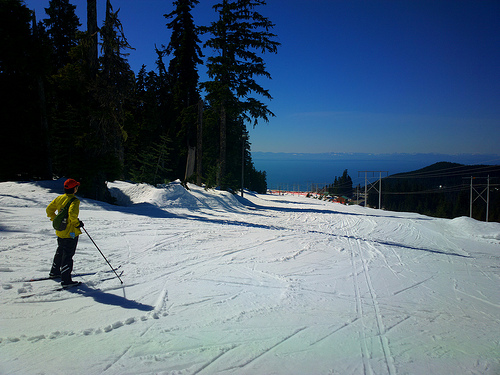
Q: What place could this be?
A: It is a field.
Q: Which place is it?
A: It is a field.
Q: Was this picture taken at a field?
A: Yes, it was taken in a field.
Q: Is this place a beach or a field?
A: It is a field.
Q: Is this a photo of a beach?
A: No, the picture is showing a field.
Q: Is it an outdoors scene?
A: Yes, it is outdoors.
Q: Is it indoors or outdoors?
A: It is outdoors.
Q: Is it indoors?
A: No, it is outdoors.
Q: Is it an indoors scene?
A: No, it is outdoors.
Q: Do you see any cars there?
A: No, there are no cars.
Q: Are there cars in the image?
A: No, there are no cars.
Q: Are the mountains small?
A: Yes, the mountains are small.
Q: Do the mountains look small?
A: Yes, the mountains are small.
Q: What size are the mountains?
A: The mountains are small.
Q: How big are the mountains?
A: The mountains are small.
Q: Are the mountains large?
A: No, the mountains are small.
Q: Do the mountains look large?
A: No, the mountains are small.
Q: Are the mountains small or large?
A: The mountains are small.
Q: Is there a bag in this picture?
A: Yes, there is a bag.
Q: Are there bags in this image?
A: Yes, there is a bag.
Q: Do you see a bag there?
A: Yes, there is a bag.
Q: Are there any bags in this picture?
A: Yes, there is a bag.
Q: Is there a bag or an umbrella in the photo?
A: Yes, there is a bag.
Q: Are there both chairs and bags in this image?
A: No, there is a bag but no chairs.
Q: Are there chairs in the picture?
A: No, there are no chairs.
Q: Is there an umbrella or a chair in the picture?
A: No, there are no chairs or umbrellas.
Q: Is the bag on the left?
A: Yes, the bag is on the left of the image.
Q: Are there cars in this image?
A: No, there are no cars.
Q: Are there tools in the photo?
A: No, there are no tools.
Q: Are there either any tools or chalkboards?
A: No, there are no tools or chalkboards.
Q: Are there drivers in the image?
A: No, there are no drivers.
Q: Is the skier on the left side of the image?
A: Yes, the skier is on the left of the image.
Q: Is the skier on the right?
A: No, the skier is on the left of the image.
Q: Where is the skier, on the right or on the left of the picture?
A: The skier is on the left of the image.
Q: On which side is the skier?
A: The skier is on the left of the image.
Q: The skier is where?
A: The skier is in the field.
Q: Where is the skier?
A: The skier is in the field.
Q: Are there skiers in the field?
A: Yes, there is a skier in the field.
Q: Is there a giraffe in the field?
A: No, there is a skier in the field.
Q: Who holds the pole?
A: The skier holds the pole.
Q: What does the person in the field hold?
A: The skier holds the pole.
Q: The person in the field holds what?
A: The skier holds the pole.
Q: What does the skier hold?
A: The skier holds the pole.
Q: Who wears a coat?
A: The skier wears a coat.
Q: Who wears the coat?
A: The skier wears a coat.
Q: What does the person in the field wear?
A: The skier wears a coat.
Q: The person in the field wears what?
A: The skier wears a coat.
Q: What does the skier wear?
A: The skier wears a coat.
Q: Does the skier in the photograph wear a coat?
A: Yes, the skier wears a coat.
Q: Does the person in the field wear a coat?
A: Yes, the skier wears a coat.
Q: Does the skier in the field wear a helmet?
A: No, the skier wears a coat.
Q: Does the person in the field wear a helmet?
A: No, the skier wears a coat.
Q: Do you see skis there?
A: Yes, there are skis.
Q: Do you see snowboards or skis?
A: Yes, there are skis.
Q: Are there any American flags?
A: No, there are no American flags.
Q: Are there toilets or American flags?
A: No, there are no American flags or toilets.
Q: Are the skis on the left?
A: Yes, the skis are on the left of the image.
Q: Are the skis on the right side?
A: No, the skis are on the left of the image.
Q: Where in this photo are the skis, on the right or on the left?
A: The skis are on the left of the image.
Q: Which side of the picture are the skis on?
A: The skis are on the left of the image.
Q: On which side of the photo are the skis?
A: The skis are on the left of the image.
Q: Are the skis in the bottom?
A: Yes, the skis are in the bottom of the image.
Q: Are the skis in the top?
A: No, the skis are in the bottom of the image.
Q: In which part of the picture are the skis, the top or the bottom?
A: The skis are in the bottom of the image.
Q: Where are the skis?
A: The skis are in the field.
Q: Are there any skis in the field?
A: Yes, there are skis in the field.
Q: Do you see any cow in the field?
A: No, there are skis in the field.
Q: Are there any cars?
A: No, there are no cars.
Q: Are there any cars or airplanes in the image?
A: No, there are no cars or airplanes.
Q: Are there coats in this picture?
A: Yes, there is a coat.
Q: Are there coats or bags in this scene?
A: Yes, there is a coat.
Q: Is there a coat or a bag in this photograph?
A: Yes, there is a coat.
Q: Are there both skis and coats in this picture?
A: Yes, there are both a coat and skis.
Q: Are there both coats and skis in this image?
A: Yes, there are both a coat and skis.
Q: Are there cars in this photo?
A: No, there are no cars.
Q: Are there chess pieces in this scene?
A: No, there are no chess pieces.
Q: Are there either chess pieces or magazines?
A: No, there are no chess pieces or magazines.